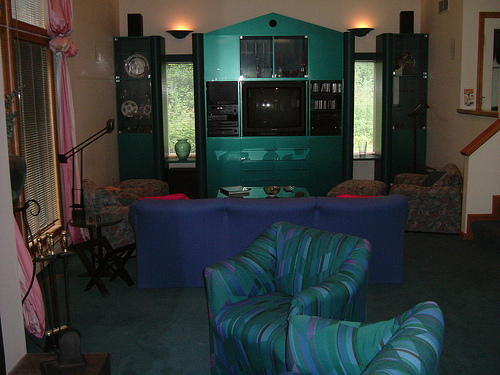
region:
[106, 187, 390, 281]
the couch is blue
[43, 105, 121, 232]
A mic stand on the table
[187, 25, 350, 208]
the entertainment center is teal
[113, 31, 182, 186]
A cabinet next to the center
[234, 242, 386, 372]
the chairs are multicolored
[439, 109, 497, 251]
The staircase is to the right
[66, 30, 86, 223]
the drapes are pink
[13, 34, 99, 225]
the drapes are open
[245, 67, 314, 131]
the TV is off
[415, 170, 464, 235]
The chairs are Camo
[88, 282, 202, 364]
the floor is carpeted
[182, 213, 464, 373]
Blue and green abstract chairs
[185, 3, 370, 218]
Green entertainment center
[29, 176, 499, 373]
Blue carpet in the house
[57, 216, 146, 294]
Brown magazine stand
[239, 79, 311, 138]
Small black tv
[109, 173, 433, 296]
Royal blue sofa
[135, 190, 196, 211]
Top of red pillow on couch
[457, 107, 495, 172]
Brown trim on stairs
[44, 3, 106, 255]
Pink and white window treatment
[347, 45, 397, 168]
Black trim on window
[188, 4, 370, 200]
a large green entertainment center with a tv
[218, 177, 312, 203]
a small green table with some items on it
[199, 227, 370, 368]
a colorful seat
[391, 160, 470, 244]
a colorful seat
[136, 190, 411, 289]
a large purple sofa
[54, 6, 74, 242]
some very tall pink and white window curtains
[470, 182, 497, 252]
some stairs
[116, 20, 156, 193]
a tall display case with some dishes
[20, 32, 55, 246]
some window blinds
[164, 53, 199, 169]
a display case with a vase inside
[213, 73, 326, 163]
a black television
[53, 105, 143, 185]
a black speaker on the wall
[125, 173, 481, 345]
a blue couch in a living room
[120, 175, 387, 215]
red pillows on a blue couch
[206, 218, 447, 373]
two blue chairs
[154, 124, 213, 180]
a green and white vase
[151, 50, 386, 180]
a green tv stand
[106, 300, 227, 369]
a blue carpet in a living room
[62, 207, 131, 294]
a wooden newspaper stand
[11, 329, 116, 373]
a brown wooden table